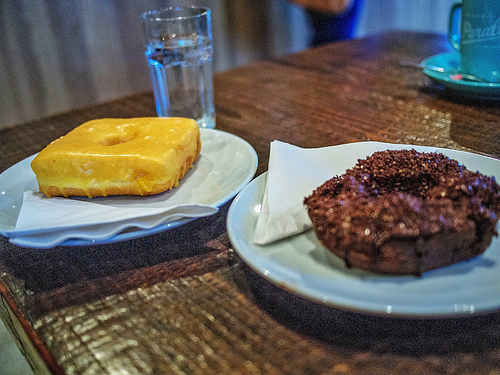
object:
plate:
[225, 141, 500, 321]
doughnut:
[29, 115, 202, 204]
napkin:
[4, 183, 222, 250]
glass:
[134, 4, 222, 130]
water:
[142, 35, 218, 131]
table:
[0, 24, 500, 374]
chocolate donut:
[304, 146, 499, 273]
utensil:
[397, 56, 486, 80]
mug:
[440, 0, 499, 85]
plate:
[1, 126, 258, 249]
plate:
[419, 47, 500, 100]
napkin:
[253, 139, 369, 249]